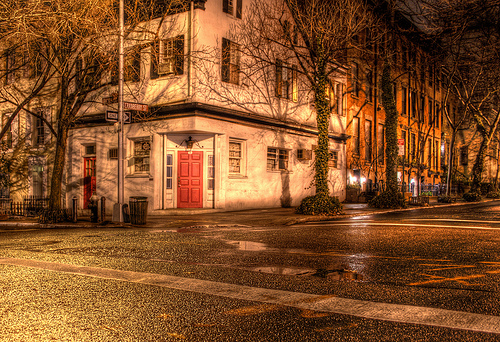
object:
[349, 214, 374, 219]
glare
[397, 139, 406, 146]
sign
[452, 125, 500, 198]
buildings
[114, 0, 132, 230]
pole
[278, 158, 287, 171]
window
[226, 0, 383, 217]
tree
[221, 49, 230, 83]
window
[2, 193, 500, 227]
sidewalk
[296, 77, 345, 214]
vines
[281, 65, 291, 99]
window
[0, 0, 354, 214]
apartment building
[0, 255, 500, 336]
line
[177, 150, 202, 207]
door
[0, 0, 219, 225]
trees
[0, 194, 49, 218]
fence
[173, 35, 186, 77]
windows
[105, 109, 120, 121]
arrow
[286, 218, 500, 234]
yellow line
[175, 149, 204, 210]
doorway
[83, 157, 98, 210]
door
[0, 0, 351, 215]
building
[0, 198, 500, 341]
lit road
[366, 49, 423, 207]
leafless tree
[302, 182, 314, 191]
leaves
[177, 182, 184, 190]
knob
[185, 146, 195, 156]
light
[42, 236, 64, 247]
puddles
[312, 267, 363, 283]
water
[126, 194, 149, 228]
trash can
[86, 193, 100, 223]
fire hydrant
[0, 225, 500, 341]
crosswalk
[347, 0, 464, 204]
building